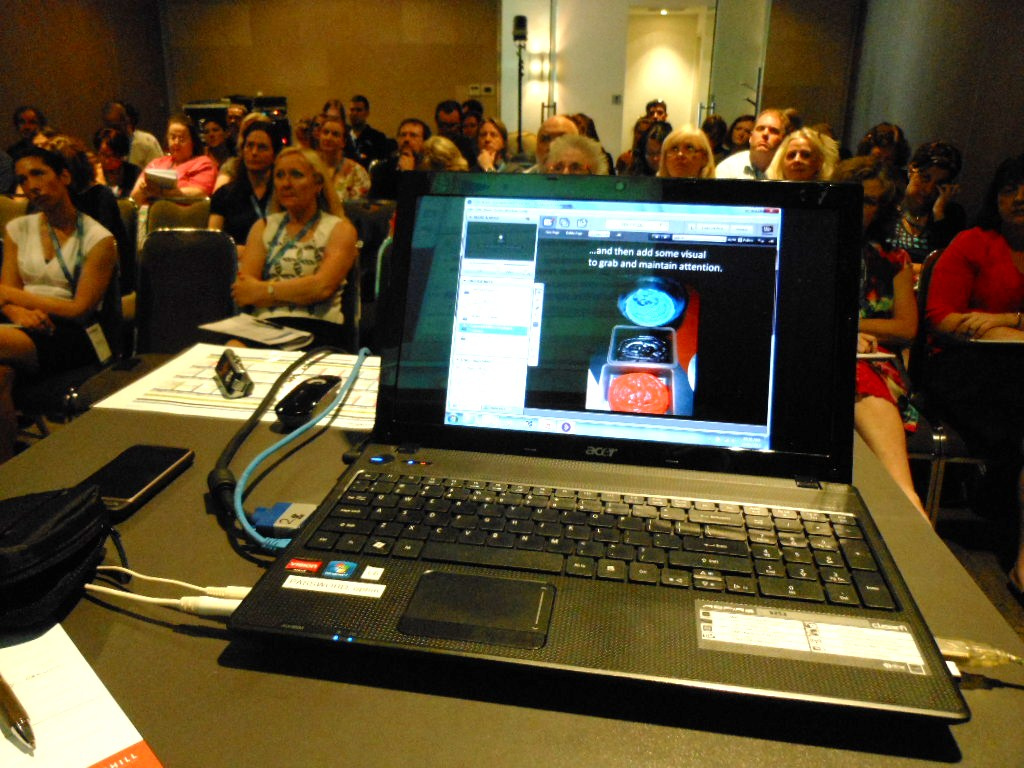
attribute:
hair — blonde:
[277, 143, 351, 223]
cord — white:
[82, 561, 248, 619]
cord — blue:
[209, 329, 387, 580]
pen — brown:
[0, 662, 36, 752]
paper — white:
[0, 613, 171, 765]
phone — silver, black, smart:
[67, 417, 201, 510]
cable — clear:
[949, 616, 1003, 696]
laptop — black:
[240, 120, 974, 751]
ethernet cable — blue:
[256, 336, 367, 570]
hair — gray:
[271, 133, 347, 222]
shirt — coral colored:
[141, 153, 219, 201]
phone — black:
[8, 443, 192, 543]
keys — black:
[484, 485, 612, 552]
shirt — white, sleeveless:
[257, 208, 342, 321]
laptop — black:
[236, 166, 982, 741]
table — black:
[6, 306, 1022, 765]